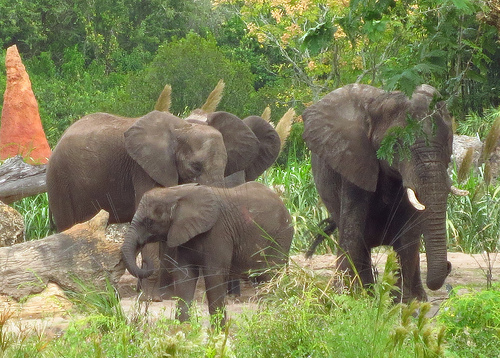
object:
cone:
[0, 42, 49, 165]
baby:
[118, 182, 290, 328]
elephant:
[302, 83, 453, 307]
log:
[0, 228, 122, 315]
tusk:
[406, 188, 426, 211]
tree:
[142, 28, 252, 121]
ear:
[300, 84, 378, 194]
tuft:
[49, 223, 55, 231]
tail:
[48, 207, 54, 231]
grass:
[231, 299, 491, 351]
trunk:
[418, 211, 452, 291]